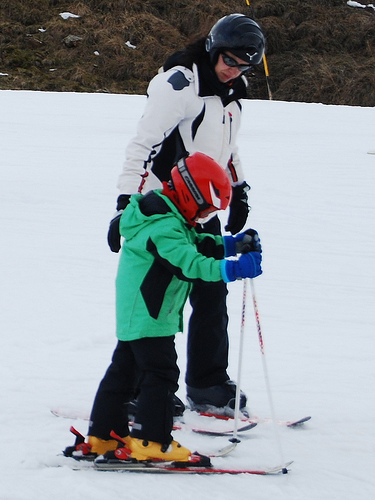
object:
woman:
[109, 10, 265, 414]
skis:
[49, 385, 312, 434]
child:
[87, 151, 232, 462]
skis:
[89, 443, 296, 477]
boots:
[123, 432, 195, 466]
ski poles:
[229, 245, 247, 446]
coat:
[105, 188, 223, 342]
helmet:
[170, 149, 233, 227]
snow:
[54, 6, 79, 24]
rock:
[60, 32, 86, 53]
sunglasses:
[219, 50, 251, 73]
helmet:
[205, 11, 265, 70]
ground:
[0, 84, 373, 499]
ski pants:
[85, 332, 181, 442]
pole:
[246, 0, 275, 103]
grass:
[1, 1, 374, 106]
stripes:
[176, 156, 207, 209]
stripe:
[154, 463, 265, 475]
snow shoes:
[187, 378, 247, 418]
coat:
[114, 42, 248, 226]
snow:
[0, 84, 375, 499]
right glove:
[222, 251, 262, 282]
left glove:
[221, 173, 251, 237]